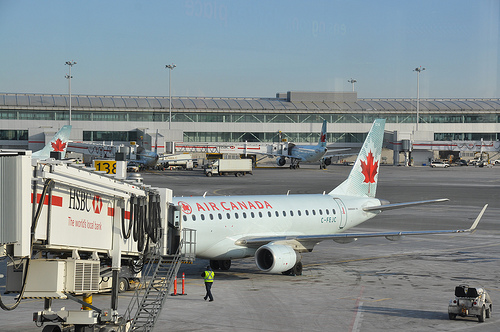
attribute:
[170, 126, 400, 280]
plane — white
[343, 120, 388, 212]
tail — orange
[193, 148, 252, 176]
truck — white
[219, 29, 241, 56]
sky — blue, bluey